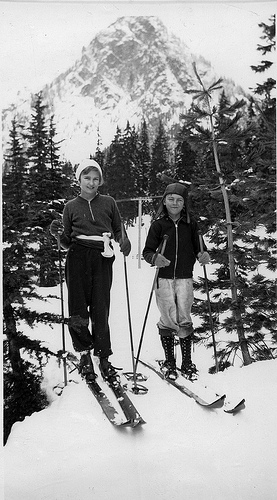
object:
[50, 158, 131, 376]
boy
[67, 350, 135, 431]
skiis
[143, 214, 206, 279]
coat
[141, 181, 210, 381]
boy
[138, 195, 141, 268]
pole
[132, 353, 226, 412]
skis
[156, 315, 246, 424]
skis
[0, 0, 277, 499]
snow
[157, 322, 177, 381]
boot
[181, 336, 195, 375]
boot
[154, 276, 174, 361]
leg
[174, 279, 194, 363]
leg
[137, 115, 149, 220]
trees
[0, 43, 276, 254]
evergreen trees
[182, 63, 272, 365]
tree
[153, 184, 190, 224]
black hat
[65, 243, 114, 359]
pants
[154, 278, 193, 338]
pants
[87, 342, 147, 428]
skis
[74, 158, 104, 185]
cap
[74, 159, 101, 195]
head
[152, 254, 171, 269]
hand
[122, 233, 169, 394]
ski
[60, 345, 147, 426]
ski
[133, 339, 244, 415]
ski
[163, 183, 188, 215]
head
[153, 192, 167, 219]
ear flaps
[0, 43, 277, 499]
ground